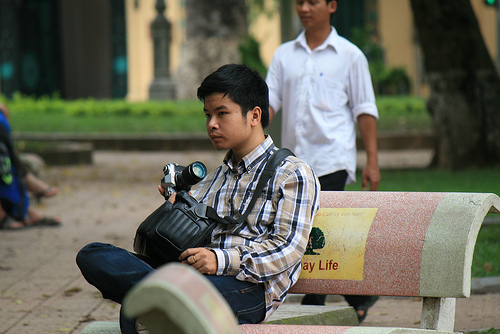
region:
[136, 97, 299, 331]
A man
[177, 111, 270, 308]
A man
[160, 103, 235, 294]
A man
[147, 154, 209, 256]
A man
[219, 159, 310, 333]
A man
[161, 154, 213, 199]
the black colored camera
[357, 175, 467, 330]
the cement bench in the park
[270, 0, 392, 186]
a man wearing white shirt walking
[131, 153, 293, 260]
a black colored camera bag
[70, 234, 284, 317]
the blue colored jeans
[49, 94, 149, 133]
the green color grass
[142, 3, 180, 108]
the old statue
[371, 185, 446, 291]
the red colored stickering on the cement bench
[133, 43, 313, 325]
a man with camera sitting on the bench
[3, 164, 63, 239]
an women with blue colored dress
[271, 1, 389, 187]
man in white shirt walking on street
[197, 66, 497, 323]
man sitting on stone bench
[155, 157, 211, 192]
professional photographer's camera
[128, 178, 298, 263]
camera case worn over man's shirt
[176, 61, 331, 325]
Asian man wearing plaid shirt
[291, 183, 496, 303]
street bench with environmentally friendly sign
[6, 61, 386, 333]
photographer sitting in the middle of park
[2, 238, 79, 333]
stone tiles with leaves scattered on them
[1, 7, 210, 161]
park with grass and yellow flower garden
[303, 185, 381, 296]
yellow sign on bench with a picture of a tree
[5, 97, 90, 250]
person wearing sandals sitting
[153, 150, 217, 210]
digital camera with zoom lens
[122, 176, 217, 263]
black camera bag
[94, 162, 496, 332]
pink and gray concrete bench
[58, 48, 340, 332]
man wearing blue jeans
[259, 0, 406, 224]
man wearing a white shirt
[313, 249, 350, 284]
the word "life"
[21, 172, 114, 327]
stone tile walkway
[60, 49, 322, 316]
he is holding a camera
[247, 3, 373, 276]
man walking through the park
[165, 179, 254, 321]
A man